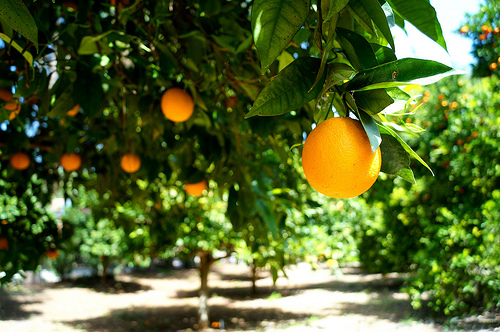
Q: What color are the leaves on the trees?
A: Green.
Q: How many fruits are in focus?
A: One.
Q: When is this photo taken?
A: Daytime.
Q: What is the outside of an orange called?
A: Peel.